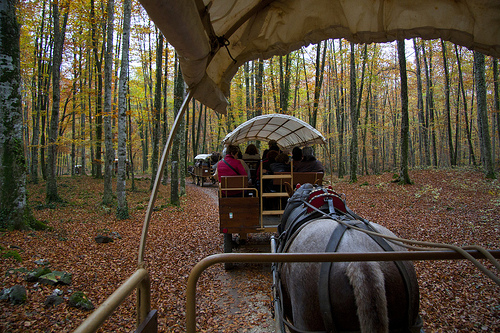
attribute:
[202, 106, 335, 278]
wagon — covered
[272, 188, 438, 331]
horse — dark brown, brown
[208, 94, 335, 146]
tarp — white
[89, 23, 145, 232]
tree — here, moldy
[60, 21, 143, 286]
leaves — red, orange, falling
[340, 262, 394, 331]
tail — here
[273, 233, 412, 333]
zebra — here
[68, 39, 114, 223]
branch — here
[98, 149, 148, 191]
cabin — here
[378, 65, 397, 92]
stem — side, here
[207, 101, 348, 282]
cart — pulled, here, wooden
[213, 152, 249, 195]
shirt — red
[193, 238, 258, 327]
metal — brown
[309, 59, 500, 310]
city — here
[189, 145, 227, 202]
trolley — horse trolley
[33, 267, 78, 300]
rock — here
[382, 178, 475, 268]
ground — here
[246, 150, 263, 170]
shirt — yellow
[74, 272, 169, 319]
rail — gold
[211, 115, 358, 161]
canopy — white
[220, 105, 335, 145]
roof — white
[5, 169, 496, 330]
leaves — orange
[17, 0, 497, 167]
leaves — yellow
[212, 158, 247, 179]
jacket — pink